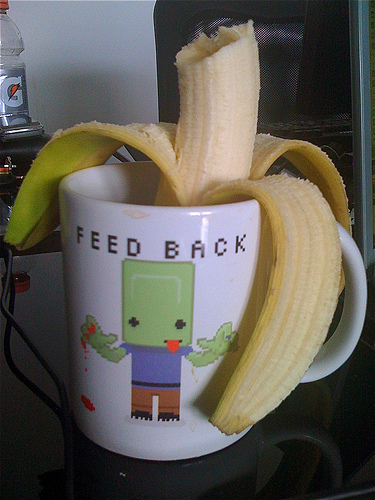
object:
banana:
[2, 14, 366, 435]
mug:
[58, 155, 368, 464]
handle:
[299, 222, 370, 383]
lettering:
[234, 233, 247, 255]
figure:
[77, 258, 242, 425]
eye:
[174, 318, 187, 330]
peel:
[209, 175, 346, 443]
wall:
[0, 0, 163, 167]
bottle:
[0, 0, 32, 126]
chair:
[233, 26, 309, 146]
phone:
[2, 121, 45, 140]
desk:
[2, 218, 375, 500]